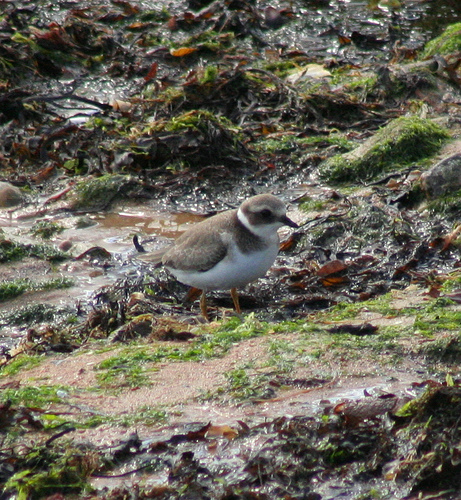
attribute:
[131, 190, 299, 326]
bird — gray, white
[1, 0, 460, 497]
ground — covered 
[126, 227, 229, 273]
wing — brown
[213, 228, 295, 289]
chest — white 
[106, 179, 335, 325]
bird — small 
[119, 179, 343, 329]
bird — white , brown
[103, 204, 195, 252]
water — brown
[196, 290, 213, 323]
leg — brown 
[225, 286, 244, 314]
leg — brown 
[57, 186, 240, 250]
water — murky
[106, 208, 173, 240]
water — dirty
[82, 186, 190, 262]
puddle — brown 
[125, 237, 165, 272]
tail feathers — gray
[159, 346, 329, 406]
ground — wet 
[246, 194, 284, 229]
head — brown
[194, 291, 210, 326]
leg — orange 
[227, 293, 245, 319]
leg — orange 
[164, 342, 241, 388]
space — brownish